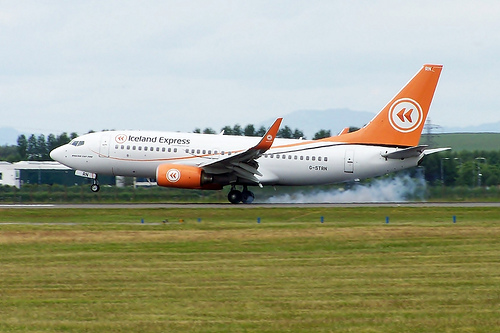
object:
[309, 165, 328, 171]
lettering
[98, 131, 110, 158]
door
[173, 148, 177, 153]
window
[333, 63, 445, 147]
tail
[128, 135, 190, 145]
logo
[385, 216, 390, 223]
marker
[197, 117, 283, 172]
wing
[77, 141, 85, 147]
windshield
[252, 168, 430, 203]
smoke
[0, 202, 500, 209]
runway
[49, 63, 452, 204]
airport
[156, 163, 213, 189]
engine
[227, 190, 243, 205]
wheel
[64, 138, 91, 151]
cabin